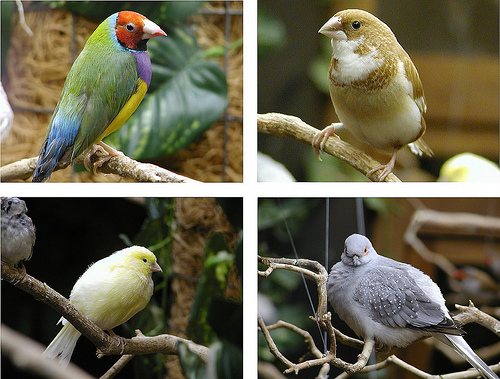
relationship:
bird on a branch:
[20, 12, 173, 179] [2, 144, 217, 182]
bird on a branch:
[40, 244, 167, 369] [3, 282, 225, 365]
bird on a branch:
[325, 233, 472, 368] [305, 328, 493, 378]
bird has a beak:
[309, 9, 435, 175] [318, 16, 352, 46]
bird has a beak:
[20, 12, 173, 179] [146, 25, 172, 39]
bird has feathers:
[20, 12, 173, 179] [45, 120, 82, 149]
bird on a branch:
[309, 9, 435, 175] [257, 112, 425, 187]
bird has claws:
[40, 244, 167, 369] [108, 334, 128, 354]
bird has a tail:
[40, 244, 167, 369] [37, 306, 87, 372]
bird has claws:
[20, 12, 173, 179] [81, 143, 137, 175]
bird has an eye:
[40, 244, 167, 369] [138, 257, 152, 271]